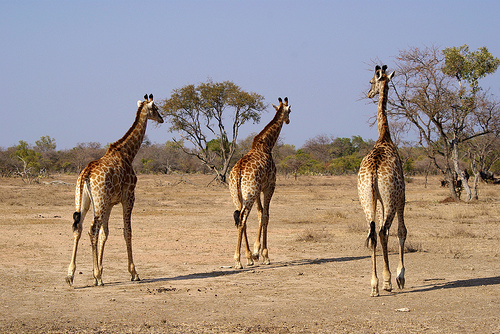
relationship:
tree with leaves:
[156, 74, 267, 186] [160, 79, 264, 120]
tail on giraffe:
[71, 163, 85, 232] [61, 89, 163, 286]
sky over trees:
[7, 6, 493, 137] [157, 45, 500, 202]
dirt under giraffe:
[6, 175, 499, 326] [353, 63, 410, 297]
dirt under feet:
[6, 175, 499, 326] [62, 245, 417, 296]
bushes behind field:
[2, 137, 494, 183] [4, 176, 499, 327]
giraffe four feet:
[61, 89, 163, 286] [61, 270, 140, 285]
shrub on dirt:
[4, 132, 55, 187] [6, 175, 499, 326]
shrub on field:
[4, 132, 55, 187] [4, 176, 499, 327]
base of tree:
[448, 163, 483, 203] [364, 38, 499, 199]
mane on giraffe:
[253, 104, 285, 151] [227, 92, 293, 271]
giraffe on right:
[355, 62, 413, 299] [342, 6, 499, 330]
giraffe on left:
[61, 89, 163, 286] [7, 8, 154, 329]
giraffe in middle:
[227, 92, 293, 271] [172, 7, 331, 332]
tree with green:
[156, 74, 267, 186] [158, 81, 268, 118]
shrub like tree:
[4, 132, 55, 187] [156, 74, 267, 186]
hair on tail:
[366, 223, 377, 246] [369, 156, 379, 248]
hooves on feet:
[66, 275, 143, 285] [61, 270, 140, 285]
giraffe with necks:
[353, 63, 410, 297] [107, 93, 405, 154]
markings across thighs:
[363, 203, 415, 245] [357, 203, 413, 242]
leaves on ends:
[160, 79, 264, 120] [163, 101, 257, 123]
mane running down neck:
[253, 104, 285, 151] [254, 115, 282, 152]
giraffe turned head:
[355, 62, 413, 299] [366, 59, 392, 104]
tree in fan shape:
[156, 74, 267, 186] [159, 80, 264, 119]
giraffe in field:
[353, 63, 410, 297] [4, 176, 499, 327]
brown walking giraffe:
[359, 62, 415, 299] [355, 62, 413, 299]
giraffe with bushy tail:
[61, 89, 163, 286] [71, 163, 85, 232]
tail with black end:
[233, 164, 244, 227] [235, 209, 240, 226]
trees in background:
[157, 45, 500, 202] [9, 8, 500, 174]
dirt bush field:
[6, 175, 499, 326] [4, 176, 499, 327]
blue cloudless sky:
[8, 7, 490, 140] [7, 6, 493, 137]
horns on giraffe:
[276, 95, 290, 106] [227, 92, 293, 271]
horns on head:
[276, 95, 290, 106] [270, 94, 294, 125]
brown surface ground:
[7, 176, 494, 328] [6, 175, 499, 326]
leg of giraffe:
[122, 202, 142, 283] [61, 89, 163, 286]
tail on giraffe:
[369, 156, 379, 248] [355, 62, 413, 299]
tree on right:
[364, 38, 499, 199] [342, 6, 499, 330]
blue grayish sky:
[8, 7, 490, 140] [7, 6, 493, 137]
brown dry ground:
[7, 176, 494, 328] [6, 175, 499, 326]